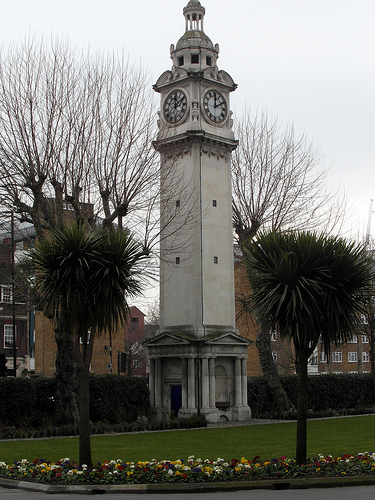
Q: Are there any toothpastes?
A: No, there are no toothpastes.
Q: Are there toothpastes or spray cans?
A: No, there are no toothpastes or spray cans.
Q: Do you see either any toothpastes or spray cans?
A: No, there are no toothpastes or spray cans.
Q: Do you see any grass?
A: Yes, there is grass.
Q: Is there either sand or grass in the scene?
A: Yes, there is grass.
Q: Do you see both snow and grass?
A: No, there is grass but no snow.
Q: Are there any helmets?
A: No, there are no helmets.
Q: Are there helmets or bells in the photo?
A: No, there are no helmets or bells.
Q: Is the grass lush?
A: Yes, the grass is lush.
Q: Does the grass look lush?
A: Yes, the grass is lush.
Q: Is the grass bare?
A: No, the grass is lush.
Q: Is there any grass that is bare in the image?
A: No, there is grass but it is lush.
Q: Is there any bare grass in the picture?
A: No, there is grass but it is lush.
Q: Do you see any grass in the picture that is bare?
A: No, there is grass but it is lush.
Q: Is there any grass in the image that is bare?
A: No, there is grass but it is lush.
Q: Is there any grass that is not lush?
A: No, there is grass but it is lush.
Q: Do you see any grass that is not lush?
A: No, there is grass but it is lush.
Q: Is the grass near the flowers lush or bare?
A: The grass is lush.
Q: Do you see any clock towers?
A: Yes, there is a clock tower.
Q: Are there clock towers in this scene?
A: Yes, there is a clock tower.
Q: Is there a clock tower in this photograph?
A: Yes, there is a clock tower.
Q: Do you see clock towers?
A: Yes, there is a clock tower.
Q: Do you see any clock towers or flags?
A: Yes, there is a clock tower.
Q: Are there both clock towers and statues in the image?
A: No, there is a clock tower but no statues.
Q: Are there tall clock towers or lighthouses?
A: Yes, there is a tall clock tower.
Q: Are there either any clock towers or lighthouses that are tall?
A: Yes, the clock tower is tall.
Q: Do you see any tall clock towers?
A: Yes, there is a tall clock tower.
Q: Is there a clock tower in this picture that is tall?
A: Yes, there is a clock tower that is tall.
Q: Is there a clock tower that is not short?
A: Yes, there is a tall clock tower.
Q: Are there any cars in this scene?
A: No, there are no cars.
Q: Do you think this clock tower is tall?
A: Yes, the clock tower is tall.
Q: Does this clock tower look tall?
A: Yes, the clock tower is tall.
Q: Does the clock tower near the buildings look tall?
A: Yes, the clock tower is tall.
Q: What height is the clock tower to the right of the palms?
A: The clock tower is tall.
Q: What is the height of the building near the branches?
A: The clock tower is tall.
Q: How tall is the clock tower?
A: The clock tower is tall.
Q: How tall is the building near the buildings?
A: The clock tower is tall.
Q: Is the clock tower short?
A: No, the clock tower is tall.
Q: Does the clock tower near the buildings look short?
A: No, the clock tower is tall.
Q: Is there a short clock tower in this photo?
A: No, there is a clock tower but it is tall.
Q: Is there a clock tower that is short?
A: No, there is a clock tower but it is tall.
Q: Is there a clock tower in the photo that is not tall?
A: No, there is a clock tower but it is tall.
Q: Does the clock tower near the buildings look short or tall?
A: The clock tower is tall.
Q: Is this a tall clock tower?
A: Yes, this is a tall clock tower.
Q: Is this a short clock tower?
A: No, this is a tall clock tower.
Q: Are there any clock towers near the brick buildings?
A: Yes, there is a clock tower near the buildings.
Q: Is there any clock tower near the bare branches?
A: Yes, there is a clock tower near the branches.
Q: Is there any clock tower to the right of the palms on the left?
A: Yes, there is a clock tower to the right of the palm trees.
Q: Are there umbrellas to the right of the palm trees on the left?
A: No, there is a clock tower to the right of the palms.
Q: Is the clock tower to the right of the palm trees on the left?
A: Yes, the clock tower is to the right of the palms.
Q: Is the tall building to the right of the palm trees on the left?
A: Yes, the clock tower is to the right of the palms.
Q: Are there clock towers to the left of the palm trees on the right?
A: Yes, there is a clock tower to the left of the palms.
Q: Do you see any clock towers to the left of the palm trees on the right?
A: Yes, there is a clock tower to the left of the palms.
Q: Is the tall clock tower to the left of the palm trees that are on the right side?
A: Yes, the clock tower is to the left of the palm trees.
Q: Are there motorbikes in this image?
A: No, there are no motorbikes.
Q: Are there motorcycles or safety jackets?
A: No, there are no motorcycles or safety jackets.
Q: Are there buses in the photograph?
A: No, there are no buses.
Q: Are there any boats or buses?
A: No, there are no buses or boats.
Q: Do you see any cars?
A: No, there are no cars.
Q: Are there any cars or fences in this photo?
A: No, there are no cars or fences.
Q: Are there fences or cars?
A: No, there are no cars or fences.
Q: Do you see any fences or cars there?
A: No, there are no cars or fences.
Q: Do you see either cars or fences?
A: No, there are no cars or fences.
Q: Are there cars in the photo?
A: No, there are no cars.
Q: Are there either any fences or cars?
A: No, there are no cars or fences.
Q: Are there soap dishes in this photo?
A: No, there are no soap dishes.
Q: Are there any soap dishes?
A: No, there are no soap dishes.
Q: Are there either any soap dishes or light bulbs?
A: No, there are no soap dishes or light bulbs.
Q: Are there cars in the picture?
A: No, there are no cars.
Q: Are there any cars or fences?
A: No, there are no cars or fences.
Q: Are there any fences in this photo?
A: No, there are no fences.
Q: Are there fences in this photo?
A: No, there are no fences.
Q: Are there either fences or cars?
A: No, there are no fences or cars.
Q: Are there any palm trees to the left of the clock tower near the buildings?
A: Yes, there are palm trees to the left of the clock tower.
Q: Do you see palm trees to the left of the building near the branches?
A: Yes, there are palm trees to the left of the clock tower.